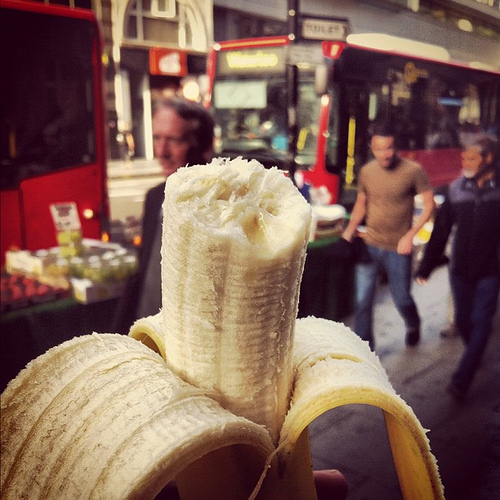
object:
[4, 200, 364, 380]
table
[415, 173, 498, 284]
shirt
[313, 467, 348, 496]
finger end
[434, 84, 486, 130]
window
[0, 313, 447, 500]
banana peel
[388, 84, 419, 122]
window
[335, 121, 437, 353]
gentleman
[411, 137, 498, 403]
gentleman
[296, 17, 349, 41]
sign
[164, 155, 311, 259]
part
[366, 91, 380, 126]
window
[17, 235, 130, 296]
produce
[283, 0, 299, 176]
black pole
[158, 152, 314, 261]
bite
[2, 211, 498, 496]
street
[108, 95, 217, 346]
man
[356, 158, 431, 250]
brown shirt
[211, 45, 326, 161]
window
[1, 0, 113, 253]
bus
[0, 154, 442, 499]
banana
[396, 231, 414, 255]
hand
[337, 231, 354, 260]
hand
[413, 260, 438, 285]
hand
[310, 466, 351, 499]
hand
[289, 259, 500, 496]
sidewalk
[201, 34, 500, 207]
bus